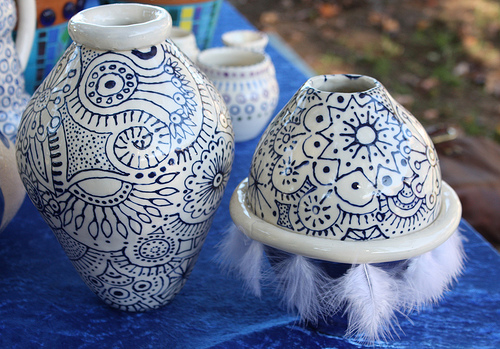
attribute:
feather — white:
[322, 261, 416, 343]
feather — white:
[259, 253, 340, 328]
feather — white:
[397, 251, 454, 315]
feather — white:
[211, 221, 269, 298]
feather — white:
[430, 229, 467, 289]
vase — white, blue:
[18, 7, 233, 307]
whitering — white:
[227, 174, 471, 264]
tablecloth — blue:
[0, 2, 498, 342]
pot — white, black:
[210, 37, 498, 324]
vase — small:
[232, 71, 477, 281]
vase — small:
[192, 36, 290, 145]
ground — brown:
[246, 3, 498, 207]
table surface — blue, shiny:
[5, 5, 490, 347]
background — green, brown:
[446, 22, 490, 129]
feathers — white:
[300, 243, 459, 332]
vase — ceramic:
[13, 3, 235, 327]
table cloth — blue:
[0, 0, 495, 342]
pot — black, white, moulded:
[11, 16, 236, 319]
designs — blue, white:
[61, 113, 189, 269]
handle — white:
[11, 0, 41, 67]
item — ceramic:
[225, 71, 464, 334]